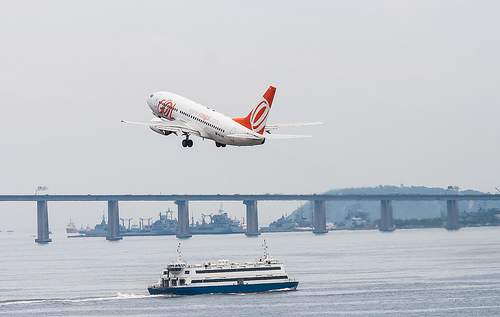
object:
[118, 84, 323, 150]
plane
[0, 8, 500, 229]
sky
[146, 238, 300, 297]
ship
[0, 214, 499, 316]
river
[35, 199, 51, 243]
column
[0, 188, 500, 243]
bridge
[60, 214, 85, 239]
ship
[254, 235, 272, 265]
antenna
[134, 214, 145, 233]
windmill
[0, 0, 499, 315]
background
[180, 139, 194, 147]
wheel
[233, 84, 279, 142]
tail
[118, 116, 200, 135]
wing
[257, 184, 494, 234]
hill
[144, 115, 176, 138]
jet engine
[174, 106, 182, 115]
window